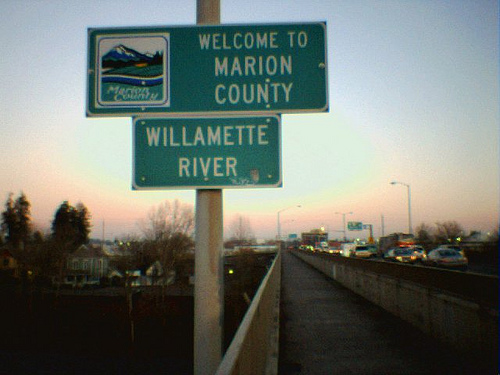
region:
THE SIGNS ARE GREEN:
[62, 9, 333, 210]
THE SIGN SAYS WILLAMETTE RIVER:
[141, 121, 288, 193]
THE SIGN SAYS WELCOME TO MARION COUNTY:
[186, 26, 317, 106]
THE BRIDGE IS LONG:
[196, 244, 498, 369]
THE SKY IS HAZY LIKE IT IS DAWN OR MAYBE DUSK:
[2, 3, 499, 257]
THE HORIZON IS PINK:
[0, 180, 499, 245]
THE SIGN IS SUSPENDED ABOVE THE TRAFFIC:
[344, 218, 379, 245]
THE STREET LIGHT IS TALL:
[390, 175, 421, 235]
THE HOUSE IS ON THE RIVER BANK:
[61, 239, 118, 304]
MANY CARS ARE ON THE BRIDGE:
[290, 228, 490, 276]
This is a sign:
[110, 56, 312, 208]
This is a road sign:
[319, 217, 396, 247]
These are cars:
[336, 240, 490, 307]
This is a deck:
[292, 236, 329, 370]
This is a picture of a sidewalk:
[250, 249, 353, 371]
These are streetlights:
[316, 175, 417, 242]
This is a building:
[61, 241, 128, 276]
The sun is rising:
[301, 165, 431, 230]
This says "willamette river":
[123, 121, 246, 198]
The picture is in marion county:
[162, 154, 395, 363]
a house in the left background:
[62, 242, 132, 286]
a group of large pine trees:
[50, 200, 93, 252]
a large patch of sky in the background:
[0, 0, 499, 242]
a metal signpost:
[192, 0, 220, 374]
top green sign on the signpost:
[85, 20, 329, 117]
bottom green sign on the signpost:
[130, 112, 282, 189]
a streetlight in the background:
[390, 180, 413, 233]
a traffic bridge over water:
[214, 242, 499, 374]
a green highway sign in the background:
[345, 220, 363, 231]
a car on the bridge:
[420, 247, 468, 273]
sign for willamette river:
[129, 113, 283, 188]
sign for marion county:
[86, 21, 329, 116]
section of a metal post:
[195, 189, 225, 374]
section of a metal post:
[193, 0, 219, 26]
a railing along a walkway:
[216, 244, 283, 374]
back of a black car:
[382, 245, 417, 265]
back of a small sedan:
[422, 246, 467, 270]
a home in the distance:
[57, 245, 105, 290]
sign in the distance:
[347, 219, 364, 230]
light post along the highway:
[390, 179, 413, 238]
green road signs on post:
[83, 18, 333, 193]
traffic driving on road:
[300, 241, 471, 269]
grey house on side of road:
[53, 241, 118, 288]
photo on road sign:
[92, 30, 173, 112]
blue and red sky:
[0, 0, 498, 243]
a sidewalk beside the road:
[265, 245, 498, 372]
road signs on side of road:
[82, 0, 332, 372]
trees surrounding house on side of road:
[0, 187, 193, 293]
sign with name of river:
[132, 114, 282, 189]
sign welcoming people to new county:
[86, 23, 331, 114]